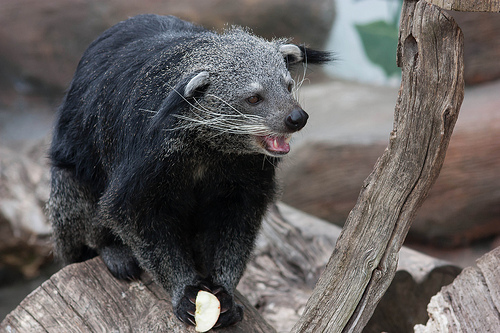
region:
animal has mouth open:
[50, 7, 310, 331]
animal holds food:
[46, 10, 309, 330]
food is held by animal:
[192, 291, 221, 328]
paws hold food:
[170, 277, 237, 332]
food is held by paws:
[190, 285, 220, 332]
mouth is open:
[246, 116, 297, 158]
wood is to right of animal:
[284, 3, 477, 330]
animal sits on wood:
[51, 6, 312, 331]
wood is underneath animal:
[0, 252, 290, 331]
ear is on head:
[277, 42, 303, 71]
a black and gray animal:
[36, 14, 321, 305]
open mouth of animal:
[254, 103, 303, 176]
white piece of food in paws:
[155, 282, 223, 332]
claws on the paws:
[181, 280, 245, 332]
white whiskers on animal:
[162, 104, 283, 154]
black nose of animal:
[287, 98, 312, 137]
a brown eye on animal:
[235, 81, 265, 116]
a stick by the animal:
[281, 18, 498, 323]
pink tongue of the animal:
[271, 140, 293, 156]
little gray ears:
[169, 37, 312, 109]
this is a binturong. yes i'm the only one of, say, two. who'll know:
[41, 14, 354, 331]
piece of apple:
[184, 286, 229, 332]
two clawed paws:
[166, 271, 245, 332]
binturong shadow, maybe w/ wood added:
[346, 256, 481, 332]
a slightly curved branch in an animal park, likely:
[274, 0, 497, 332]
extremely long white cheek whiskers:
[124, 71, 273, 157]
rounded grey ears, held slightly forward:
[169, 38, 319, 103]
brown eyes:
[244, 79, 297, 109]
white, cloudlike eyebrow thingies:
[235, 67, 292, 97]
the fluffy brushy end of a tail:
[259, 31, 350, 74]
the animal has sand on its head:
[172, 16, 316, 173]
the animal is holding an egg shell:
[164, 276, 246, 328]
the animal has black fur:
[46, 8, 335, 332]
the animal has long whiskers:
[143, 78, 265, 150]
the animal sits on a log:
[11, 23, 292, 330]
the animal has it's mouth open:
[251, 115, 307, 160]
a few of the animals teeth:
[268, 139, 290, 150]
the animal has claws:
[173, 272, 235, 329]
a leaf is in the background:
[357, 13, 429, 78]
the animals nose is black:
[284, 105, 313, 133]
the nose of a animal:
[270, 86, 345, 134]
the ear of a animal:
[160, 35, 235, 101]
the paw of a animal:
[155, 250, 242, 327]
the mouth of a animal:
[234, 97, 329, 172]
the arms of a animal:
[94, 138, 213, 325]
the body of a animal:
[57, 0, 293, 274]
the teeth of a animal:
[260, 99, 333, 164]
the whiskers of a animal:
[183, 87, 279, 164]